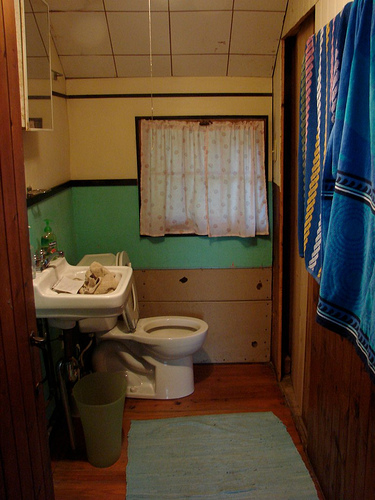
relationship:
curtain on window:
[130, 111, 273, 243] [135, 113, 272, 250]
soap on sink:
[41, 218, 57, 261] [34, 250, 134, 321]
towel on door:
[297, 9, 346, 287] [298, 19, 361, 484]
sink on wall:
[31, 255, 134, 334] [0, 81, 81, 421]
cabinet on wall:
[130, 265, 275, 361] [3, 64, 92, 448]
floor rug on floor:
[122, 408, 320, 498] [49, 359, 327, 498]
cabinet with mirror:
[12, 2, 59, 133] [19, 2, 53, 132]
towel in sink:
[87, 262, 111, 296] [42, 237, 134, 323]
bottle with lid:
[38, 216, 53, 258] [41, 214, 51, 233]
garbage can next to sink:
[72, 371, 129, 468] [36, 244, 126, 323]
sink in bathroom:
[31, 255, 134, 338] [8, 4, 372, 492]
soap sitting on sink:
[41, 218, 57, 261] [38, 241, 151, 341]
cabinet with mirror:
[13, 0, 55, 136] [17, 0, 55, 129]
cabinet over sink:
[13, 0, 55, 136] [31, 232, 153, 317]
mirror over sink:
[17, 0, 55, 129] [31, 232, 153, 317]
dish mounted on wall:
[27, 185, 49, 196] [17, 1, 78, 467]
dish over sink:
[27, 185, 49, 196] [28, 248, 134, 317]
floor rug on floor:
[125, 411, 320, 499] [130, 365, 318, 497]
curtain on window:
[137, 118, 270, 240] [135, 113, 272, 250]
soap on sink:
[44, 223, 54, 254] [31, 245, 131, 332]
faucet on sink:
[31, 245, 52, 270] [29, 245, 135, 337]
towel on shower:
[309, 57, 364, 178] [304, 35, 371, 328]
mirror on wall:
[17, 0, 55, 129] [32, 143, 52, 186]